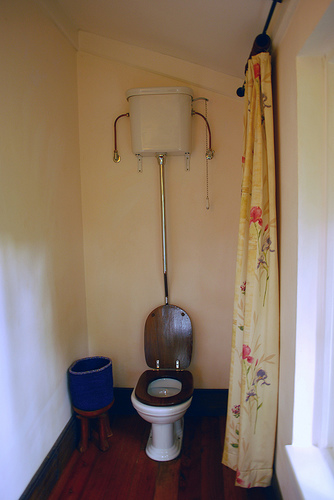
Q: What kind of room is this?
A: It is a bathroom.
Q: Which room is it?
A: It is a bathroom.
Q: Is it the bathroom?
A: Yes, it is the bathroom.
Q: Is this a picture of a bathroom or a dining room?
A: It is showing a bathroom.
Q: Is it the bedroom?
A: No, it is the bathroom.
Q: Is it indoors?
A: Yes, it is indoors.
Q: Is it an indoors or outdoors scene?
A: It is indoors.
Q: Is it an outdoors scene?
A: No, it is indoors.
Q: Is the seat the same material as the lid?
A: Yes, both the seat and the lid are made of wood.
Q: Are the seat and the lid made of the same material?
A: Yes, both the seat and the lid are made of wood.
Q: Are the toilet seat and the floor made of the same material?
A: Yes, both the seat and the floor are made of wood.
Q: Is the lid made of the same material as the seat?
A: Yes, both the lid and the seat are made of wood.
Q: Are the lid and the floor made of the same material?
A: Yes, both the lid and the floor are made of wood.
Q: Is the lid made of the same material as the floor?
A: Yes, both the lid and the floor are made of wood.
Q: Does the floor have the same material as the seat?
A: Yes, both the floor and the seat are made of wood.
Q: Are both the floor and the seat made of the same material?
A: Yes, both the floor and the seat are made of wood.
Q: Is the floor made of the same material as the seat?
A: Yes, both the floor and the seat are made of wood.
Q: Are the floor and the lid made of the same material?
A: Yes, both the floor and the lid are made of wood.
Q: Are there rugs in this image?
A: No, there are no rugs.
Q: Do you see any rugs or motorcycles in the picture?
A: No, there are no rugs or motorcycles.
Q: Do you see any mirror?
A: No, there are no mirrors.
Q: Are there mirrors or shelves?
A: No, there are no mirrors or shelves.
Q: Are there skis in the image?
A: No, there are no skis.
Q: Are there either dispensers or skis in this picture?
A: No, there are no skis or dispensers.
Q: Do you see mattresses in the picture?
A: No, there are no mattresses.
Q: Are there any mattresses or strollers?
A: No, there are no mattresses or strollers.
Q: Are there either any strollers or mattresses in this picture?
A: No, there are no mattresses or strollers.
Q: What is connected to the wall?
A: The pipe is connected to the wall.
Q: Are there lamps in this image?
A: No, there are no lamps.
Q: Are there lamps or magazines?
A: No, there are no lamps or magazines.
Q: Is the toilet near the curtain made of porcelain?
A: Yes, the toilet is made of porcelain.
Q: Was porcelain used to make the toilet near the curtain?
A: Yes, the toilet is made of porcelain.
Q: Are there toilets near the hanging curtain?
A: Yes, there is a toilet near the curtain.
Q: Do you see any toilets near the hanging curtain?
A: Yes, there is a toilet near the curtain.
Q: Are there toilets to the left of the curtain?
A: Yes, there is a toilet to the left of the curtain.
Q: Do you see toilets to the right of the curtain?
A: No, the toilet is to the left of the curtain.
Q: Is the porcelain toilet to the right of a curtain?
A: No, the toilet is to the left of a curtain.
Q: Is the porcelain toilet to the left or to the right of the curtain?
A: The toilet is to the left of the curtain.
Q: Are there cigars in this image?
A: No, there are no cigars.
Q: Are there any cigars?
A: No, there are no cigars.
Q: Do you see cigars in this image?
A: No, there are no cigars.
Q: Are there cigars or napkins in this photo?
A: No, there are no cigars or napkins.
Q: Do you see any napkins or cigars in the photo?
A: No, there are no cigars or napkins.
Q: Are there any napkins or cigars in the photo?
A: No, there are no cigars or napkins.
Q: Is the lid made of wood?
A: Yes, the lid is made of wood.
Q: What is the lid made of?
A: The lid is made of wood.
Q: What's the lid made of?
A: The lid is made of wood.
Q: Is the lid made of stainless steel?
A: No, the lid is made of wood.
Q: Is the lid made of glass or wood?
A: The lid is made of wood.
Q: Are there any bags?
A: No, there are no bags.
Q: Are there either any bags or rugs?
A: No, there are no bags or rugs.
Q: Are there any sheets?
A: No, there are no sheets.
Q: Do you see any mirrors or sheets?
A: No, there are no sheets or mirrors.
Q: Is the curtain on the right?
A: Yes, the curtain is on the right of the image.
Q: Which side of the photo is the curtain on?
A: The curtain is on the right of the image.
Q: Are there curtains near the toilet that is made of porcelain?
A: Yes, there is a curtain near the toilet.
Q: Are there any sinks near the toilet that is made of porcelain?
A: No, there is a curtain near the toilet.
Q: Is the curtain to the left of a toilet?
A: No, the curtain is to the right of a toilet.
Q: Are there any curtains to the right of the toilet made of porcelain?
A: Yes, there is a curtain to the right of the toilet.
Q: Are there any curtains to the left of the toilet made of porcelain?
A: No, the curtain is to the right of the toilet.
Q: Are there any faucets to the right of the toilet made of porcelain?
A: No, there is a curtain to the right of the toilet.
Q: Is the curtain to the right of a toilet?
A: Yes, the curtain is to the right of a toilet.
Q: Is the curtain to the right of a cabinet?
A: No, the curtain is to the right of a toilet.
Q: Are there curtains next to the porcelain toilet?
A: Yes, there is a curtain next to the toilet.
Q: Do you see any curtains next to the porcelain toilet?
A: Yes, there is a curtain next to the toilet.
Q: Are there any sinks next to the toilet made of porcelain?
A: No, there is a curtain next to the toilet.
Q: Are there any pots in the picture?
A: No, there are no pots.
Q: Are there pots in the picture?
A: No, there are no pots.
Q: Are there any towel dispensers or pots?
A: No, there are no pots or towel dispensers.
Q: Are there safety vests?
A: No, there are no safety vests.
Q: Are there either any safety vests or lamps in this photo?
A: No, there are no safety vests or lamps.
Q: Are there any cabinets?
A: No, there are no cabinets.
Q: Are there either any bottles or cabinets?
A: No, there are no cabinets or bottles.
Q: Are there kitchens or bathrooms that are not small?
A: No, there is a bathroom but it is small.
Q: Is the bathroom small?
A: Yes, the bathroom is small.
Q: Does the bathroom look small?
A: Yes, the bathroom is small.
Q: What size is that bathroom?
A: The bathroom is small.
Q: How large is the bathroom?
A: The bathroom is small.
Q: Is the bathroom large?
A: No, the bathroom is small.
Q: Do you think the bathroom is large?
A: No, the bathroom is small.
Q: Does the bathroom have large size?
A: No, the bathroom is small.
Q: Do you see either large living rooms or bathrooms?
A: No, there is a bathroom but it is small.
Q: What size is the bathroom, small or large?
A: The bathroom is small.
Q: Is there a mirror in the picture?
A: No, there are no mirrors.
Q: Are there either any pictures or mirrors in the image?
A: No, there are no mirrors or pictures.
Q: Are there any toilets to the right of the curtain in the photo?
A: No, the toilet is to the left of the curtain.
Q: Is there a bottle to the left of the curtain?
A: No, there is a toilet to the left of the curtain.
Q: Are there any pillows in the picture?
A: No, there are no pillows.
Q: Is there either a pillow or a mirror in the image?
A: No, there are no pillows or mirrors.